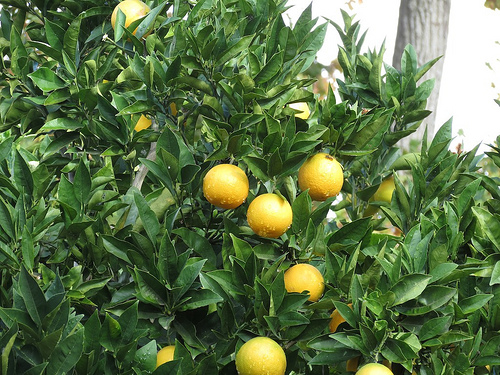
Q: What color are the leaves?
A: Green.